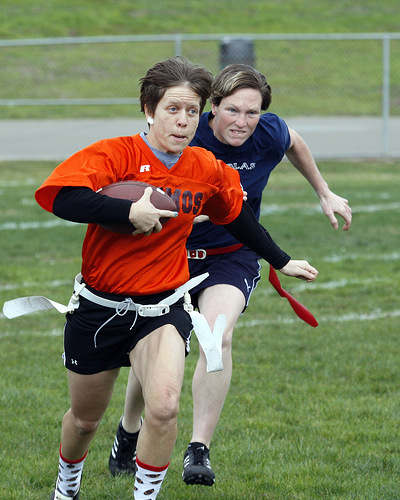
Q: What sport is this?
A: Football.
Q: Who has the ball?
A: Boy in orange shirt.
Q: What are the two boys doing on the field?
A: Running.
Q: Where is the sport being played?
A: Green field.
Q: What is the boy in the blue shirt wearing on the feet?
A: Cleats.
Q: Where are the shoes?
A: On man.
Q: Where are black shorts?
A: On man.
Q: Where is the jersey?
A: On man.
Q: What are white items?
A: Flags.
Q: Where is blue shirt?
A: On man.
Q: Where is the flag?
A: On man.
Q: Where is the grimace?
A: On face.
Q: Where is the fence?
A: By field.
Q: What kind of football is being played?
A: Flag football.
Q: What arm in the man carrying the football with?
A: Right arm.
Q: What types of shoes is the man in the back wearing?
A: Cleats.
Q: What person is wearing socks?
A: The person in front.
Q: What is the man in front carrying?
A: A football.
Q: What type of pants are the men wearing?
A: Shorts.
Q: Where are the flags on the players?
A: At the hips.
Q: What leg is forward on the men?
A: Left leg.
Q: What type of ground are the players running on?
A: Grass.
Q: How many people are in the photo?
A: Two.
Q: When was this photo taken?
A: Daytime.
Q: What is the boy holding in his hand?
A: Football.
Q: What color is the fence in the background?
A: Silver.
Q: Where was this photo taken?
A: At a football game.